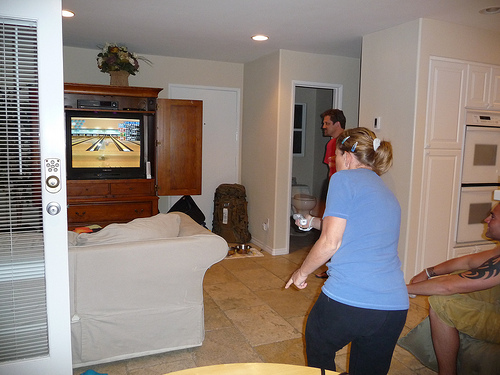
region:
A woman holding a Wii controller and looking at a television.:
[281, 123, 407, 373]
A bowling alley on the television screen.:
[67, 115, 137, 166]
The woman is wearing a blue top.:
[320, 168, 410, 312]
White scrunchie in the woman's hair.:
[370, 136, 380, 151]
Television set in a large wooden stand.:
[57, 84, 202, 227]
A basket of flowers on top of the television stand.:
[93, 44, 150, 88]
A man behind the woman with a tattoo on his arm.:
[396, 198, 498, 374]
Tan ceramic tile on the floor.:
[69, 244, 494, 374]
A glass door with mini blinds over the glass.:
[0, 27, 70, 374]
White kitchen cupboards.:
[409, 54, 499, 288]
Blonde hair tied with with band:
[329, 123, 400, 174]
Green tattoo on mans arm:
[458, 256, 498, 289]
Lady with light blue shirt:
[321, 170, 409, 315]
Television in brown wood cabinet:
[63, 82, 205, 216]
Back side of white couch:
[69, 215, 234, 365]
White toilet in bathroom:
[291, 175, 315, 213]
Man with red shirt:
[319, 103, 346, 173]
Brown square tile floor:
[211, 268, 279, 356]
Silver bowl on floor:
[235, 243, 251, 255]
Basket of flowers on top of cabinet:
[94, 45, 139, 88]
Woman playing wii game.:
[277, 107, 414, 373]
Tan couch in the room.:
[1, 208, 233, 366]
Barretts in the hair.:
[337, 129, 361, 154]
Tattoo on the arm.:
[452, 250, 497, 287]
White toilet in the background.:
[289, 175, 316, 226]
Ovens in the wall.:
[453, 120, 498, 250]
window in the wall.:
[294, 95, 306, 159]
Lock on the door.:
[40, 150, 64, 195]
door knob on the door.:
[45, 200, 64, 219]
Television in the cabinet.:
[64, 105, 152, 181]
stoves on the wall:
[462, 113, 499, 235]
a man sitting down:
[423, 207, 498, 329]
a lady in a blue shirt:
[306, 135, 412, 364]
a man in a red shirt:
[317, 111, 344, 170]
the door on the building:
[6, 70, 68, 372]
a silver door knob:
[44, 200, 59, 210]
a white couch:
[71, 230, 220, 345]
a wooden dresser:
[69, 79, 180, 216]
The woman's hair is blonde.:
[333, 122, 397, 172]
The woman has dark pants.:
[302, 287, 412, 372]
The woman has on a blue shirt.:
[316, 167, 415, 314]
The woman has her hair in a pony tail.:
[333, 125, 395, 175]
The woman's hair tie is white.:
[367, 134, 381, 153]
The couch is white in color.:
[87, 256, 202, 336]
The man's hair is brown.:
[320, 102, 347, 137]